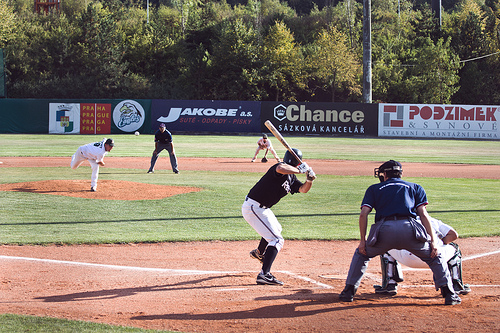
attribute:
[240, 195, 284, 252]
pants — white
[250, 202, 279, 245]
stripe — black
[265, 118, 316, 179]
bat — wood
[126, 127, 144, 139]
ball — white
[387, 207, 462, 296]
uniform — white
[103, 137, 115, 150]
cap — black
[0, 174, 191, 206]
mound — pitcher's mound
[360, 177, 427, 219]
shirt — blue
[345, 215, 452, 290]
pants — gray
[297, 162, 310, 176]
hand — man's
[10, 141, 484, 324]
field — green, baseball field